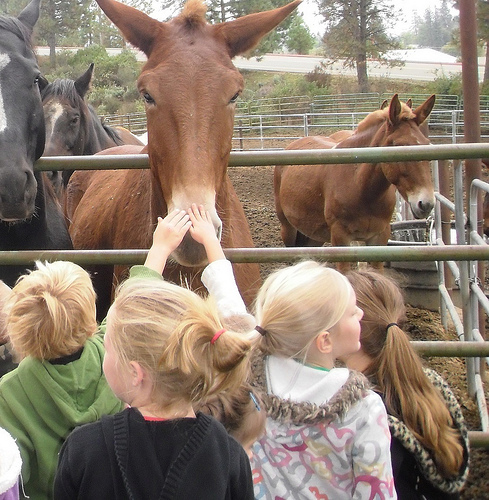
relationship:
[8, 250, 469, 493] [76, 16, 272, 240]
children observing animals